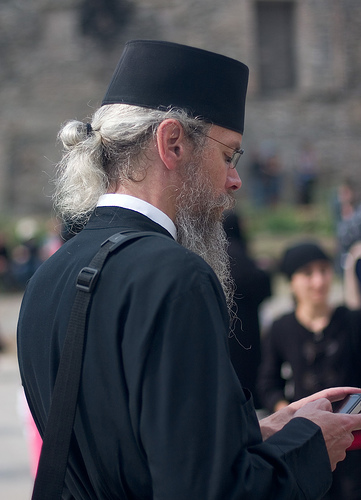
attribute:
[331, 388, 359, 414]
phone — mobile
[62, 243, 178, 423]
strap — black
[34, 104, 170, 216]
hair — grey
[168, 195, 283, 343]
beard — long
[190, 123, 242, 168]
glasses — wire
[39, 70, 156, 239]
hair — long, grey, back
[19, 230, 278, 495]
suit — man, black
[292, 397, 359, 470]
hand — man's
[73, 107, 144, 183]
hair — grey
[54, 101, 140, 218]
style — grey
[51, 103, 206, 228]
hair — long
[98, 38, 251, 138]
hat — black, sturdy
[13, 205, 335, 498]
jacket — man's, navy-blue, suit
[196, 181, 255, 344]
beard — grey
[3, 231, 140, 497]
strap — black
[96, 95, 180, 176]
hair — grey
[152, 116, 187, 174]
ear — man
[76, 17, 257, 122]
hat — black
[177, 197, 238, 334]
beard — long, grey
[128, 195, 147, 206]
shirt — dressy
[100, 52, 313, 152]
cap — flat top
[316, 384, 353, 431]
device — mobile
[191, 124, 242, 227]
face — man's